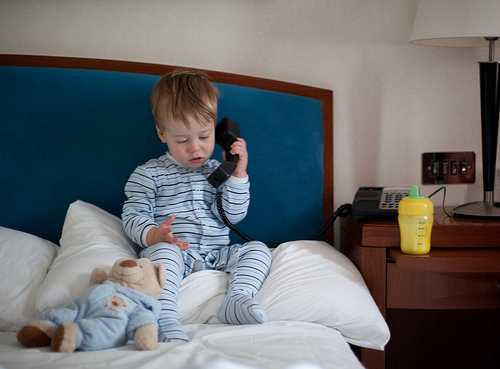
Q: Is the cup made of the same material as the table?
A: No, the cup is made of plastic and the table is made of wood.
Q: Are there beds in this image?
A: Yes, there is a bed.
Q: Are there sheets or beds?
A: Yes, there is a bed.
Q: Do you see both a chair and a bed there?
A: No, there is a bed but no chairs.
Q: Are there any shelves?
A: No, there are no shelves.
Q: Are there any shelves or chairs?
A: No, there are no shelves or chairs.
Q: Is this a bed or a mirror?
A: This is a bed.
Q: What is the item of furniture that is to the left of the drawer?
A: The piece of furniture is a bed.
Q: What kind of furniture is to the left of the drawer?
A: The piece of furniture is a bed.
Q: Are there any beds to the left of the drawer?
A: Yes, there is a bed to the left of the drawer.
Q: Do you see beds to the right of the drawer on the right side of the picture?
A: No, the bed is to the left of the drawer.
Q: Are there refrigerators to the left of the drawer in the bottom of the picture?
A: No, there is a bed to the left of the drawer.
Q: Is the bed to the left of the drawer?
A: Yes, the bed is to the left of the drawer.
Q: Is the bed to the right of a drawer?
A: No, the bed is to the left of a drawer.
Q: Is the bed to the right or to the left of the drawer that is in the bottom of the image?
A: The bed is to the left of the drawer.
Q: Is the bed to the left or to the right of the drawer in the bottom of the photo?
A: The bed is to the left of the drawer.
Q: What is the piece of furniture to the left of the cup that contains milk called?
A: The piece of furniture is a bed.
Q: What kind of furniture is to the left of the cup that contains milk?
A: The piece of furniture is a bed.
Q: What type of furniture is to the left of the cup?
A: The piece of furniture is a bed.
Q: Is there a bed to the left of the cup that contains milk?
A: Yes, there is a bed to the left of the cup.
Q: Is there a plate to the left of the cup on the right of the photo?
A: No, there is a bed to the left of the cup.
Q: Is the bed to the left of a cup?
A: Yes, the bed is to the left of a cup.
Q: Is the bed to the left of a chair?
A: No, the bed is to the left of a cup.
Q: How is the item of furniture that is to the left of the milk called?
A: The piece of furniture is a bed.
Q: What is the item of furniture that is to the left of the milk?
A: The piece of furniture is a bed.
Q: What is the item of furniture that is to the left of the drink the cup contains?
A: The piece of furniture is a bed.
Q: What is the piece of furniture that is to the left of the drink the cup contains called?
A: The piece of furniture is a bed.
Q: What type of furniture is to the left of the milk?
A: The piece of furniture is a bed.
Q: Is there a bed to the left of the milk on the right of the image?
A: Yes, there is a bed to the left of the milk.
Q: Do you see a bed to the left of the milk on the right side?
A: Yes, there is a bed to the left of the milk.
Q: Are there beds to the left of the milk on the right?
A: Yes, there is a bed to the left of the milk.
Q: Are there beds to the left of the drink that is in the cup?
A: Yes, there is a bed to the left of the milk.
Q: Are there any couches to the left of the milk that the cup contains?
A: No, there is a bed to the left of the milk.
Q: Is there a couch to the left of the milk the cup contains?
A: No, there is a bed to the left of the milk.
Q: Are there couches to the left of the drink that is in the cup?
A: No, there is a bed to the left of the milk.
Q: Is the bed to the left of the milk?
A: Yes, the bed is to the left of the milk.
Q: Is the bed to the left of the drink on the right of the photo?
A: Yes, the bed is to the left of the milk.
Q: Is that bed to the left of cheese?
A: No, the bed is to the left of the milk.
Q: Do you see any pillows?
A: Yes, there is a pillow.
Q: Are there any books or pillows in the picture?
A: Yes, there is a pillow.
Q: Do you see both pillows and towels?
A: No, there is a pillow but no towels.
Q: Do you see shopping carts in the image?
A: No, there are no shopping carts.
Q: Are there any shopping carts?
A: No, there are no shopping carts.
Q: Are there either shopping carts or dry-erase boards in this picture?
A: No, there are no shopping carts or dry-erase boards.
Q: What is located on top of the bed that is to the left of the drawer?
A: The pillow is on top of the bed.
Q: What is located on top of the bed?
A: The pillow is on top of the bed.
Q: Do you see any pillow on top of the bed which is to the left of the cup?
A: Yes, there is a pillow on top of the bed.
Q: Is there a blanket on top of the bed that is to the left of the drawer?
A: No, there is a pillow on top of the bed.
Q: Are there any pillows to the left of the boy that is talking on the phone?
A: Yes, there is a pillow to the left of the boy.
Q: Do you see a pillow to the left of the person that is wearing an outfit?
A: Yes, there is a pillow to the left of the boy.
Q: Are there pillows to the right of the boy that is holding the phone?
A: No, the pillow is to the left of the boy.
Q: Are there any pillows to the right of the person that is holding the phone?
A: No, the pillow is to the left of the boy.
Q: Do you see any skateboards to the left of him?
A: No, there is a pillow to the left of the boy.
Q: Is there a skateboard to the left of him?
A: No, there is a pillow to the left of the boy.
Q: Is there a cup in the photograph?
A: Yes, there is a cup.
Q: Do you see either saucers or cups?
A: Yes, there is a cup.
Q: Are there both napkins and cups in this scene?
A: No, there is a cup but no napkins.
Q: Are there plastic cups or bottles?
A: Yes, there is a plastic cup.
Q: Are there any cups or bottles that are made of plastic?
A: Yes, the cup is made of plastic.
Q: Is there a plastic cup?
A: Yes, there is a cup that is made of plastic.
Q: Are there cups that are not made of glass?
A: Yes, there is a cup that is made of plastic.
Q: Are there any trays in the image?
A: No, there are no trays.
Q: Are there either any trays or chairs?
A: No, there are no trays or chairs.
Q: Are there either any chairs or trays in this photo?
A: No, there are no trays or chairs.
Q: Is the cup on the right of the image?
A: Yes, the cup is on the right of the image.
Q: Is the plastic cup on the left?
A: No, the cup is on the right of the image.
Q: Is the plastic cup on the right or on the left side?
A: The cup is on the right of the image.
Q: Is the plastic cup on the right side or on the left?
A: The cup is on the right of the image.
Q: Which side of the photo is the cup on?
A: The cup is on the right of the image.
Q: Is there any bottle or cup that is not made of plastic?
A: No, there is a cup but it is made of plastic.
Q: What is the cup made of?
A: The cup is made of plastic.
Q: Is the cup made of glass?
A: No, the cup is made of plastic.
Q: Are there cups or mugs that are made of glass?
A: No, there is a cup but it is made of plastic.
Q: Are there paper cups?
A: No, there is a cup but it is made of plastic.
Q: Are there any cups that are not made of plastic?
A: No, there is a cup but it is made of plastic.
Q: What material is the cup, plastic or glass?
A: The cup is made of plastic.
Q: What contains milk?
A: The cup contains milk.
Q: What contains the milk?
A: The cup contains milk.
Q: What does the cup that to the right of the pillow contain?
A: The cup contains milk.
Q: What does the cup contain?
A: The cup contains milk.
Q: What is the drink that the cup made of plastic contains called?
A: The drink is milk.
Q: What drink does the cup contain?
A: The cup contains milk.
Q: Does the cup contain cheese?
A: No, the cup contains milk.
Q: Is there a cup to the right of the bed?
A: Yes, there is a cup to the right of the bed.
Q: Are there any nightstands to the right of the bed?
A: No, there is a cup to the right of the bed.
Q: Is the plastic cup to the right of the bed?
A: Yes, the cup is to the right of the bed.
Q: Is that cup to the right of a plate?
A: No, the cup is to the right of the bed.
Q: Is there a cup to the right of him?
A: Yes, there is a cup to the right of the boy.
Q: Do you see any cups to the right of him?
A: Yes, there is a cup to the right of the boy.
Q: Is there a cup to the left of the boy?
A: No, the cup is to the right of the boy.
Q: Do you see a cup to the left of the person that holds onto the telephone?
A: No, the cup is to the right of the boy.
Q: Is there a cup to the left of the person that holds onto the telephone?
A: No, the cup is to the right of the boy.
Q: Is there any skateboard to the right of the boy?
A: No, there is a cup to the right of the boy.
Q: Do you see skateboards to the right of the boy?
A: No, there is a cup to the right of the boy.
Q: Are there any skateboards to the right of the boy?
A: No, there is a cup to the right of the boy.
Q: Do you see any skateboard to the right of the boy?
A: No, there is a cup to the right of the boy.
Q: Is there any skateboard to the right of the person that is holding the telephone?
A: No, there is a cup to the right of the boy.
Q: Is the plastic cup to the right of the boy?
A: Yes, the cup is to the right of the boy.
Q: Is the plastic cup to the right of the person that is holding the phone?
A: Yes, the cup is to the right of the boy.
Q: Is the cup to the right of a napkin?
A: No, the cup is to the right of the boy.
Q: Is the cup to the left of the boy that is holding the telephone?
A: No, the cup is to the right of the boy.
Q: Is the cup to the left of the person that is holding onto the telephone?
A: No, the cup is to the right of the boy.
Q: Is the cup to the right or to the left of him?
A: The cup is to the right of the boy.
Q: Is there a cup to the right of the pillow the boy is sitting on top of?
A: Yes, there is a cup to the right of the pillow.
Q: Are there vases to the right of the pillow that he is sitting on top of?
A: No, there is a cup to the right of the pillow.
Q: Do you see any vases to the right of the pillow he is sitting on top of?
A: No, there is a cup to the right of the pillow.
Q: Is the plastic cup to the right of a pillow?
A: Yes, the cup is to the right of a pillow.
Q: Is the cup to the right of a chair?
A: No, the cup is to the right of a pillow.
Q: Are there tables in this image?
A: Yes, there is a table.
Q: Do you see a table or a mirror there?
A: Yes, there is a table.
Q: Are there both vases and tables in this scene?
A: No, there is a table but no vases.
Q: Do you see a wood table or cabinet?
A: Yes, there is a wood table.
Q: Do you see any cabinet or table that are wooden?
A: Yes, the table is wooden.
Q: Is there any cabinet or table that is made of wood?
A: Yes, the table is made of wood.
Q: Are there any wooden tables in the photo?
A: Yes, there is a wood table.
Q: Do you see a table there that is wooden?
A: Yes, there is a table that is wooden.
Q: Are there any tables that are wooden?
A: Yes, there is a table that is wooden.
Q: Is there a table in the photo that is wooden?
A: Yes, there is a table that is wooden.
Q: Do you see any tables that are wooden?
A: Yes, there is a table that is wooden.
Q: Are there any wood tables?
A: Yes, there is a table that is made of wood.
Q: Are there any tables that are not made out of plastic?
A: Yes, there is a table that is made of wood.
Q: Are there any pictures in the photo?
A: No, there are no pictures.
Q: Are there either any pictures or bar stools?
A: No, there are no pictures or bar stools.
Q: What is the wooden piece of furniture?
A: The piece of furniture is a table.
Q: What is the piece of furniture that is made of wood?
A: The piece of furniture is a table.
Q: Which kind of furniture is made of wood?
A: The furniture is a table.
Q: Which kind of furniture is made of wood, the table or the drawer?
A: The table is made of wood.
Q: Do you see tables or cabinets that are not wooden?
A: No, there is a table but it is wooden.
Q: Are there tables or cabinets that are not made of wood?
A: No, there is a table but it is made of wood.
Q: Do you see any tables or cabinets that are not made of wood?
A: No, there is a table but it is made of wood.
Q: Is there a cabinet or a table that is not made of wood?
A: No, there is a table but it is made of wood.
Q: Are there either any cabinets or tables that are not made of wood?
A: No, there is a table but it is made of wood.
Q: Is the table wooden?
A: Yes, the table is wooden.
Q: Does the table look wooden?
A: Yes, the table is wooden.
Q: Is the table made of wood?
A: Yes, the table is made of wood.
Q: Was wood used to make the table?
A: Yes, the table is made of wood.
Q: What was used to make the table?
A: The table is made of wood.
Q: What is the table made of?
A: The table is made of wood.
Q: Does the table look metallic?
A: No, the table is wooden.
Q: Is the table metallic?
A: No, the table is wooden.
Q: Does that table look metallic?
A: No, the table is wooden.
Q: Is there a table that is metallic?
A: No, there is a table but it is wooden.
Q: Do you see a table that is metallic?
A: No, there is a table but it is wooden.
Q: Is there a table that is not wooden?
A: No, there is a table but it is wooden.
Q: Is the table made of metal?
A: No, the table is made of wood.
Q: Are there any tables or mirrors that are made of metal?
A: No, there is a table but it is made of wood.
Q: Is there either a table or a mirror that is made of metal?
A: No, there is a table but it is made of wood.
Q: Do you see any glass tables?
A: No, there is a table but it is made of wood.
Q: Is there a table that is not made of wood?
A: No, there is a table but it is made of wood.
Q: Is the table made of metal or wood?
A: The table is made of wood.